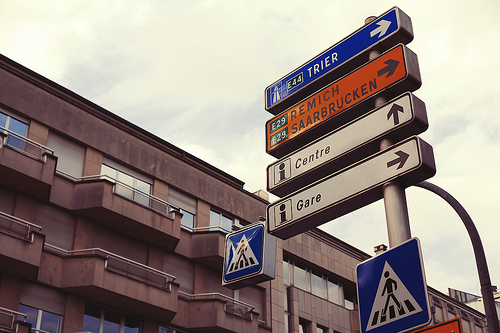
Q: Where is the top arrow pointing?
A: Right.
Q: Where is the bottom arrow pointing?
A: Right.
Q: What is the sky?
A: Cloudy.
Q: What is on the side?
A: Balconies.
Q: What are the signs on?
A: Pole.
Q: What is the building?
A: Brown.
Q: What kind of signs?
A: Street signs.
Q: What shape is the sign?
A: Square.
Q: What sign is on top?
A: Blue.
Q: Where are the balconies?
A: Building.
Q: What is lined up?
A: The long horizontal signs.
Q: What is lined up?
A: Four signs.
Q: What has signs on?
A: The metal pole.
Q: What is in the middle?
A: The red sign.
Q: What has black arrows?
A: The white signs.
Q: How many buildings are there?
A: 1.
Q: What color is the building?
A: Brown.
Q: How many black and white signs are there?
A: 2.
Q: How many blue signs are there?
A: 3.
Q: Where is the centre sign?
A: Above the gare sign.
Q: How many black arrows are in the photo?
A: 3.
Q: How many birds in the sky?
A: 0.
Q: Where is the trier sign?
A: Above the orange sign.